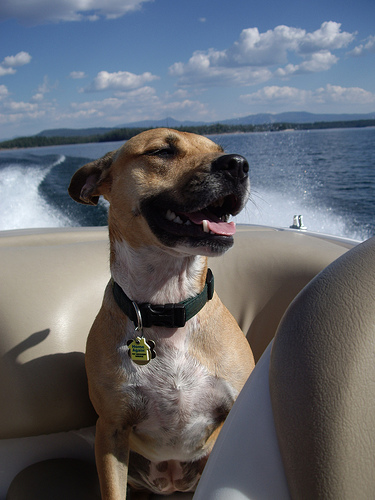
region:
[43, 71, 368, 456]
Dog in an inflatable on a lake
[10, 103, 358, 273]
Dog looking happy in an inflatable on the ocean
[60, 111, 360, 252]
Dog with mouth open looking over a lake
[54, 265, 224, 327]
Green dog collar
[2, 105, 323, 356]
Brown and white dog in an inflatable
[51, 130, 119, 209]
Brown dog ear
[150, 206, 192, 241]
White dog molars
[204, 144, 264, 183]
Black dog nose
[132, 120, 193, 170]
Black dog eye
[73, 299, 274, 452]
White furry dog chest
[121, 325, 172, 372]
dog wearing dog tags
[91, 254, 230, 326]
dog collar is green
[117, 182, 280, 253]
dog's mouth is open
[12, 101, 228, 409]
dog in a boat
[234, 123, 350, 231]
splashing from the boat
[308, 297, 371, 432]
boat interior is tan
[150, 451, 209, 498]
dog has spots on her belly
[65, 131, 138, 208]
dog's ear is back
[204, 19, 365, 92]
white puffy clouds in sky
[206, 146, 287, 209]
dog's nose is black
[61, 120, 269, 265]
the head of a dog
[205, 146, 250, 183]
the nose of a dog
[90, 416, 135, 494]
the leg of a dog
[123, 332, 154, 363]
a tag on the collar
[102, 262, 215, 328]
a collar on the dog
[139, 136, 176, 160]
the eye of the dog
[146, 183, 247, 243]
the mouth of the dog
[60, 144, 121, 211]
the ear of the dog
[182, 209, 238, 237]
the tongue of the dog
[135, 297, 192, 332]
a black clasp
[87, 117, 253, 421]
the dog is on a boat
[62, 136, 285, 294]
the dog is happy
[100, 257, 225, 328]
the dog wears a collar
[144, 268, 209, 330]
the collar is green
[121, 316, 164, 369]
the dog has tags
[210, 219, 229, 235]
the dog has a tongue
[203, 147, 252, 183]
the dog has a nose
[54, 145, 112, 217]
the dog has an ear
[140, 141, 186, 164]
the dog has an eye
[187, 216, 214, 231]
the dog has a tooth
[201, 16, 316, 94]
clouds in the sky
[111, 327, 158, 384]
collar around dog's neck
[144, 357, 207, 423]
white part of dog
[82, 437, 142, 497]
leg of the dog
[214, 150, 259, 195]
nose of the dog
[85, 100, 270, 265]
head of the dog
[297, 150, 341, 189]
water next to the boat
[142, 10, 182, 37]
blue sky behind clouds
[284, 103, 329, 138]
trees in the distance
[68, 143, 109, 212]
ear of the dog